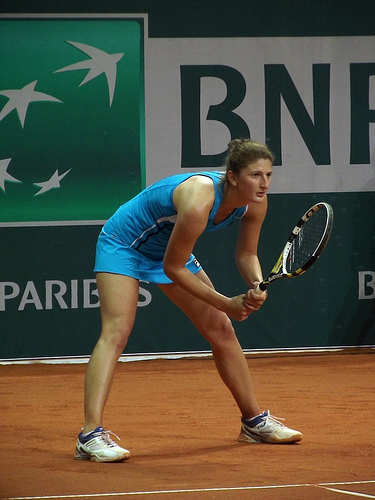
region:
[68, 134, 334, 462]
person is playing tennis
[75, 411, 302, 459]
player is wearing white and blue shoes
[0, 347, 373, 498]
tennis court is red and white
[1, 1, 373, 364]
dark green back wall behind person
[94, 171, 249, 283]
player is wearing light blue clothing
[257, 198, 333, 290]
tennis racket is black, yellow, and white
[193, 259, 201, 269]
black tag on players shorts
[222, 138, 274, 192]
hair is pulled tightly up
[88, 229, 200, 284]
player is wearing blue skirt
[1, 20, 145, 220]
large light green logo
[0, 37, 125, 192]
white stars on the wall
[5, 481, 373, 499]
white boundary lines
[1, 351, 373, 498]
brown tennis court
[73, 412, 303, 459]
white and blue tennis shoes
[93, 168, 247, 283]
blue tennis clothing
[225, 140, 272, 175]
woman's hair is in a bun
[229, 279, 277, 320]
both hands on the handle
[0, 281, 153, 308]
white text on the wall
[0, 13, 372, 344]
a green and white advertisement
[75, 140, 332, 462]
the woman is playing tennis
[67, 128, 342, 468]
A woman is playing tennis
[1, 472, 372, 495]
White lines on the tennis court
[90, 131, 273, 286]
Woman's outfit is blue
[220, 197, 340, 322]
A tennis racket in two hands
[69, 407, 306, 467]
A pair of white sneakers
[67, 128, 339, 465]
The tennis player is bent over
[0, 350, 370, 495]
The tennis court is clay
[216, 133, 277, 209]
Woman's brown hair is in a bun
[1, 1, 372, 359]
A wall is behind the player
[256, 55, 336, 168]
The lettert "N" on the wall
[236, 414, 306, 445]
a woman's white tennis shoe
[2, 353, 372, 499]
part of a tennis court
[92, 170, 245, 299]
a woman's blue dress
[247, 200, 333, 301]
a black, white and yellow racket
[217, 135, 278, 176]
a woman's blonde hair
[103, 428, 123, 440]
a white shoe string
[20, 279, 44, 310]
a white capital letter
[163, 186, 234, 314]
the arm of a woman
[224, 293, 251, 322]
the hand of a woman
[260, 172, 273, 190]
the nose of a woman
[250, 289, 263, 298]
person has a finger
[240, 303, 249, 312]
person has a finger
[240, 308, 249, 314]
person has a finger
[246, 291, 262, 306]
person has a finger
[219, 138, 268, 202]
the head of a woman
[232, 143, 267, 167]
the hair of a woman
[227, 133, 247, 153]
the bun of a woman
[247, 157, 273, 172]
the forehead of a woman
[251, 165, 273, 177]
the eyebrows of a woman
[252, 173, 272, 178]
the eyes of a woman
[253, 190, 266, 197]
the mouth of a woman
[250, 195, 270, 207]
the chin of a woman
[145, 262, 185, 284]
the elbow of a woman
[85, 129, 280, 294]
Tennis player wearing a blue outfit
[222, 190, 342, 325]
Tennis racket in two hands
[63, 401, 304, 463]
A pair of white sneakers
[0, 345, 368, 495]
A clay tennis court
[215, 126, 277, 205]
Woman has brown hair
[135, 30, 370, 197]
Green writing on white sign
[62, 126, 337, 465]
A tennis player is bent over